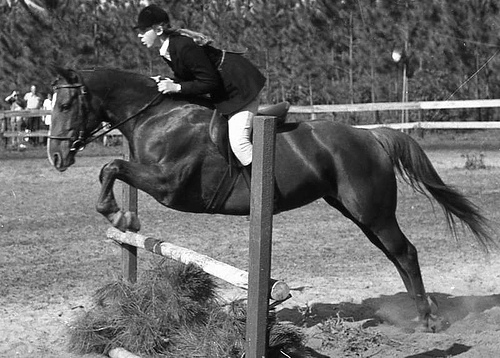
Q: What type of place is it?
A: It is a field.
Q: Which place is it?
A: It is a field.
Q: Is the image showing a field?
A: Yes, it is showing a field.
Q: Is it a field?
A: Yes, it is a field.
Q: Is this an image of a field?
A: Yes, it is showing a field.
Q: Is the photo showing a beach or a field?
A: It is showing a field.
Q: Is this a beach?
A: No, it is a field.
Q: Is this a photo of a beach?
A: No, the picture is showing a field.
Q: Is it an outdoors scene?
A: Yes, it is outdoors.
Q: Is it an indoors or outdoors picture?
A: It is outdoors.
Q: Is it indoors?
A: No, it is outdoors.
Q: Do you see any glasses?
A: No, there are no glasses.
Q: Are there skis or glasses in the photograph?
A: No, there are no glasses or skis.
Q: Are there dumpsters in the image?
A: No, there are no dumpsters.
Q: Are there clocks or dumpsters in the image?
A: No, there are no dumpsters or clocks.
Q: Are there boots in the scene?
A: Yes, there are boots.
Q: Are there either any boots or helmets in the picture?
A: Yes, there are boots.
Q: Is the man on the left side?
A: Yes, the man is on the left of the image.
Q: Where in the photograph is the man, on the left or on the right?
A: The man is on the left of the image.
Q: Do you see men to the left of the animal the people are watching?
A: Yes, there is a man to the left of the horse.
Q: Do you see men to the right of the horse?
A: No, the man is to the left of the horse.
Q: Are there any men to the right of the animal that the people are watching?
A: No, the man is to the left of the horse.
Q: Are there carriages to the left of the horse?
A: No, there is a man to the left of the horse.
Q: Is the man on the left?
A: Yes, the man is on the left of the image.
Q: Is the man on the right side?
A: No, the man is on the left of the image.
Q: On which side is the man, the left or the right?
A: The man is on the left of the image.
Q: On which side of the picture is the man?
A: The man is on the left of the image.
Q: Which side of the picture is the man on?
A: The man is on the left of the image.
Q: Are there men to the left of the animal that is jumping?
A: Yes, there is a man to the left of the horse.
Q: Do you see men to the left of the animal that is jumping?
A: Yes, there is a man to the left of the horse.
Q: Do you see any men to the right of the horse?
A: No, the man is to the left of the horse.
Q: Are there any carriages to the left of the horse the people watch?
A: No, there is a man to the left of the horse.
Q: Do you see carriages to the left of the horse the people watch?
A: No, there is a man to the left of the horse.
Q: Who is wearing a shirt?
A: The man is wearing a shirt.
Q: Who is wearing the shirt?
A: The man is wearing a shirt.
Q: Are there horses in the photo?
A: Yes, there is a horse.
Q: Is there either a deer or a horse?
A: Yes, there is a horse.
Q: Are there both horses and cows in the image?
A: No, there is a horse but no cows.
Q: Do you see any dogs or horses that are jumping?
A: Yes, the horse is jumping.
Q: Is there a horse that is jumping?
A: Yes, there is a horse that is jumping.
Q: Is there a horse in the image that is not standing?
A: Yes, there is a horse that is jumping.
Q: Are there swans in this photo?
A: No, there are no swans.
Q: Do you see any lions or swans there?
A: No, there are no swans or lions.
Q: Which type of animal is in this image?
A: The animal is a horse.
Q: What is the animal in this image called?
A: The animal is a horse.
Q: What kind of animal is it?
A: The animal is a horse.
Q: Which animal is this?
A: That is a horse.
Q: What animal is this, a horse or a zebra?
A: That is a horse.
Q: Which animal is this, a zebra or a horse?
A: That is a horse.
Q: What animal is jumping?
A: The animal is a horse.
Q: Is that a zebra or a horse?
A: That is a horse.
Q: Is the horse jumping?
A: Yes, the horse is jumping.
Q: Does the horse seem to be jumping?
A: Yes, the horse is jumping.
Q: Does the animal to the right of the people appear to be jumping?
A: Yes, the horse is jumping.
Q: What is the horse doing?
A: The horse is jumping.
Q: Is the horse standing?
A: No, the horse is jumping.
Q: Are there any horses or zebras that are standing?
A: No, there is a horse but it is jumping.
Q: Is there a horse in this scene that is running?
A: No, there is a horse but it is jumping.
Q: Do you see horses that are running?
A: No, there is a horse but it is jumping.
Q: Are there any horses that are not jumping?
A: No, there is a horse but it is jumping.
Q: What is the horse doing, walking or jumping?
A: The horse is jumping.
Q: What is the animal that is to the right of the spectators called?
A: The animal is a horse.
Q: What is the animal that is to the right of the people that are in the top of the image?
A: The animal is a horse.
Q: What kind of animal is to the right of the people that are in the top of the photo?
A: The animal is a horse.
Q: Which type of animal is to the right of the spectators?
A: The animal is a horse.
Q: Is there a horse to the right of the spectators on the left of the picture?
A: Yes, there is a horse to the right of the spectators.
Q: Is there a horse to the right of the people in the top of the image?
A: Yes, there is a horse to the right of the spectators.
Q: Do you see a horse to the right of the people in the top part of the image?
A: Yes, there is a horse to the right of the spectators.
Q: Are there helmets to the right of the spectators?
A: No, there is a horse to the right of the spectators.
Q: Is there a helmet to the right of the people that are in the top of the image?
A: No, there is a horse to the right of the spectators.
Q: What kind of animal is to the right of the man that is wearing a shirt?
A: The animal is a horse.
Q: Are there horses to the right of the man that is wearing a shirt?
A: Yes, there is a horse to the right of the man.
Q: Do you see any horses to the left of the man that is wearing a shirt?
A: No, the horse is to the right of the man.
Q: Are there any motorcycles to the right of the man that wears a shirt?
A: No, there is a horse to the right of the man.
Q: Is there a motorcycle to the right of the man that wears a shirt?
A: No, there is a horse to the right of the man.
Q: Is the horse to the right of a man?
A: Yes, the horse is to the right of a man.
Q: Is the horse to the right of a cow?
A: No, the horse is to the right of a man.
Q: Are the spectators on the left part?
A: Yes, the spectators are on the left of the image.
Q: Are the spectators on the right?
A: No, the spectators are on the left of the image.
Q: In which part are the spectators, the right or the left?
A: The spectators are on the left of the image.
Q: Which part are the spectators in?
A: The spectators are on the left of the image.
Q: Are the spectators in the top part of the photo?
A: Yes, the spectators are in the top of the image.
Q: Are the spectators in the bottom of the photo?
A: No, the spectators are in the top of the image.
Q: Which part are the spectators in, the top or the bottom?
A: The spectators are in the top of the image.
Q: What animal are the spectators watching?
A: The spectators are watching the horse.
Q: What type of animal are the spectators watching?
A: The spectators are watching the horse.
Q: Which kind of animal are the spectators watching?
A: The spectators are watching the horse.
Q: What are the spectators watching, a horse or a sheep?
A: The spectators are watching a horse.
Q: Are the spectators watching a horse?
A: Yes, the spectators are watching a horse.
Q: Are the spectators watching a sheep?
A: No, the spectators are watching a horse.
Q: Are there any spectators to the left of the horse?
A: Yes, there are spectators to the left of the horse.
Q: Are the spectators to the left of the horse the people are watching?
A: Yes, the spectators are to the left of the horse.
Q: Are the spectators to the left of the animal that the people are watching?
A: Yes, the spectators are to the left of the horse.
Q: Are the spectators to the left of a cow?
A: No, the spectators are to the left of the horse.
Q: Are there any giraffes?
A: No, there are no giraffes.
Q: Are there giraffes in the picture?
A: No, there are no giraffes.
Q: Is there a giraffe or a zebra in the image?
A: No, there are no giraffes or zebras.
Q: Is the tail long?
A: Yes, the tail is long.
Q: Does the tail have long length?
A: Yes, the tail is long.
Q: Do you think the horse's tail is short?
A: No, the tail is long.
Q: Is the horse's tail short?
A: No, the tail is long.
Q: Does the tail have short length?
A: No, the tail is long.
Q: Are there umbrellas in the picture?
A: No, there are no umbrellas.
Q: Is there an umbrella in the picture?
A: No, there are no umbrellas.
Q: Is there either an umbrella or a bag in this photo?
A: No, there are no umbrellas or bags.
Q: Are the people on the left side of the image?
A: Yes, the people are on the left of the image.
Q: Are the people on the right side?
A: No, the people are on the left of the image.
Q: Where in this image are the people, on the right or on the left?
A: The people are on the left of the image.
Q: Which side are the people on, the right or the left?
A: The people are on the left of the image.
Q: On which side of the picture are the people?
A: The people are on the left of the image.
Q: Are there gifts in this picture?
A: No, there are no gifts.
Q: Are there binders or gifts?
A: No, there are no gifts or binders.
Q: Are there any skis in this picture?
A: No, there are no skis.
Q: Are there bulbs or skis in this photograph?
A: No, there are no skis or bulbs.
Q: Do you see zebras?
A: No, there are no zebras.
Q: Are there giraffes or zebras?
A: No, there are no zebras or giraffes.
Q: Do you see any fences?
A: Yes, there is a fence.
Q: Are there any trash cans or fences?
A: Yes, there is a fence.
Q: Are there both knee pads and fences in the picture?
A: No, there is a fence but no knee pads.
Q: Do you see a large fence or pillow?
A: Yes, there is a large fence.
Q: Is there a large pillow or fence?
A: Yes, there is a large fence.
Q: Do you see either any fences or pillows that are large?
A: Yes, the fence is large.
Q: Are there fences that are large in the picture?
A: Yes, there is a large fence.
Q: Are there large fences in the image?
A: Yes, there is a large fence.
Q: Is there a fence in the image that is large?
A: Yes, there is a fence that is large.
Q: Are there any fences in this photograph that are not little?
A: Yes, there is a large fence.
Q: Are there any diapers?
A: No, there are no diapers.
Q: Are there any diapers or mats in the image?
A: No, there are no diapers or mats.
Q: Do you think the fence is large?
A: Yes, the fence is large.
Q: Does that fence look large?
A: Yes, the fence is large.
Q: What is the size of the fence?
A: The fence is large.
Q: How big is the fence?
A: The fence is large.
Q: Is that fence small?
A: No, the fence is large.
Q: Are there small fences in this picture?
A: No, there is a fence but it is large.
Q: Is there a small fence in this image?
A: No, there is a fence but it is large.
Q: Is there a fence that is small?
A: No, there is a fence but it is large.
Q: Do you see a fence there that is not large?
A: No, there is a fence but it is large.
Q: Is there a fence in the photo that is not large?
A: No, there is a fence but it is large.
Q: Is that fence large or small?
A: The fence is large.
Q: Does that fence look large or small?
A: The fence is large.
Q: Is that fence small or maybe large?
A: The fence is large.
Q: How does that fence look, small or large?
A: The fence is large.